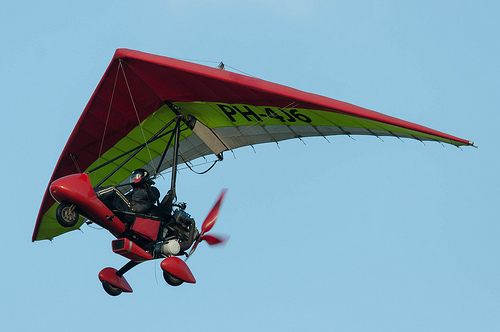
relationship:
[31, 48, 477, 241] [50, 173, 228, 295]
kite attached to a car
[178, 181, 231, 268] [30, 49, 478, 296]
propellor on aircraft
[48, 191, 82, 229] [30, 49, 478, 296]
tire on aircraft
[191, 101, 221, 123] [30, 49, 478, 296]
yellow part of aircraft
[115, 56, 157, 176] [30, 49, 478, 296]
strings holding aircraft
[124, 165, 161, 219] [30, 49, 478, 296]
man flying ultralight aircraft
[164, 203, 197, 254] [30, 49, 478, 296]
engine of ultralight aircraft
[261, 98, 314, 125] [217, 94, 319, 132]
numbers and letters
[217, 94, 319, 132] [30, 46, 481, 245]
letters on wing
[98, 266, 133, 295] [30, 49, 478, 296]
gear wheel on aircraft